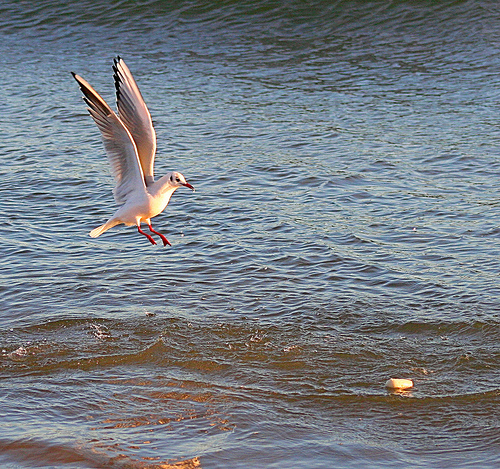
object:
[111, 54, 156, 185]
wings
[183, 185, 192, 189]
bill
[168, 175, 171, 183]
spot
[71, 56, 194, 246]
bird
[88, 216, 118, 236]
tail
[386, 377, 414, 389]
chunk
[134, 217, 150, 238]
leg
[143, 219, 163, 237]
left leg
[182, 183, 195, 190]
beak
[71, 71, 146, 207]
wings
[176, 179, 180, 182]
eye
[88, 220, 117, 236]
tail feathers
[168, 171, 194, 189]
head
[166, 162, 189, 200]
face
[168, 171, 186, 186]
face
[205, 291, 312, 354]
ripples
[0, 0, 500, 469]
water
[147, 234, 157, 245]
foot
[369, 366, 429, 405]
something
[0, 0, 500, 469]
ripple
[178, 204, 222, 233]
air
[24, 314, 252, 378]
waves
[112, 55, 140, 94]
up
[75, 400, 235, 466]
light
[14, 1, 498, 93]
shadow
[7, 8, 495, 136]
back